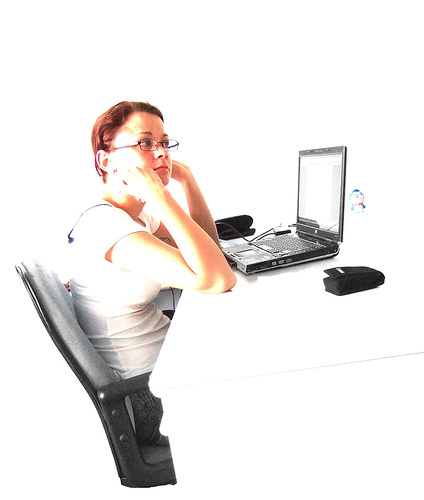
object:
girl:
[86, 121, 182, 329]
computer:
[220, 146, 345, 274]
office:
[47, 21, 397, 475]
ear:
[95, 146, 120, 172]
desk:
[143, 195, 422, 499]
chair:
[8, 246, 219, 499]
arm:
[92, 179, 238, 291]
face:
[123, 109, 191, 193]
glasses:
[98, 137, 189, 158]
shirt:
[55, 204, 169, 386]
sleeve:
[100, 218, 151, 255]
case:
[321, 265, 385, 297]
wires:
[203, 222, 284, 247]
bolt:
[108, 405, 122, 422]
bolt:
[117, 429, 133, 448]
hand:
[109, 161, 166, 203]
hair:
[78, 93, 173, 177]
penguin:
[351, 185, 367, 217]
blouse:
[60, 195, 184, 373]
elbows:
[208, 243, 238, 298]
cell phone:
[323, 263, 387, 299]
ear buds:
[65, 227, 76, 242]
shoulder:
[86, 197, 151, 269]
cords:
[224, 220, 291, 238]